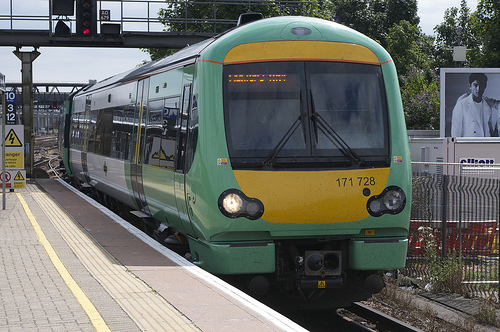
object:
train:
[58, 15, 415, 307]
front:
[216, 39, 408, 221]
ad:
[439, 66, 499, 137]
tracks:
[316, 301, 425, 331]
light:
[222, 193, 243, 214]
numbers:
[335, 176, 375, 187]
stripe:
[14, 189, 112, 299]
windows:
[76, 94, 179, 171]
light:
[83, 28, 91, 35]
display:
[227, 73, 288, 83]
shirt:
[450, 92, 496, 137]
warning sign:
[0, 128, 25, 190]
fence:
[411, 171, 499, 302]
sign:
[4, 90, 17, 125]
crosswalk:
[0, 0, 228, 48]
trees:
[141, 0, 499, 128]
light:
[383, 188, 404, 211]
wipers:
[258, 86, 365, 170]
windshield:
[224, 62, 391, 171]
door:
[128, 76, 151, 216]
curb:
[0, 242, 166, 331]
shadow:
[36, 176, 179, 269]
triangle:
[1, 128, 23, 148]